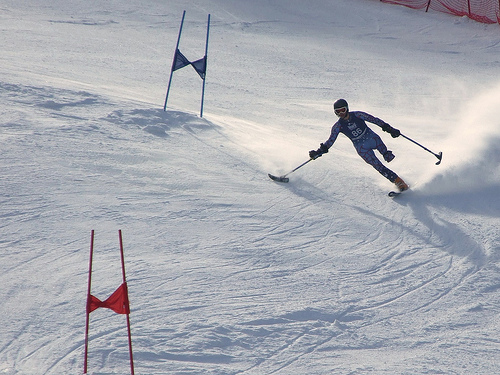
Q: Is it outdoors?
A: Yes, it is outdoors.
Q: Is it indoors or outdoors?
A: It is outdoors.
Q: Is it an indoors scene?
A: No, it is outdoors.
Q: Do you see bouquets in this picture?
A: No, there are no bouquets.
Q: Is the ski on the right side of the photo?
A: Yes, the ski is on the right of the image.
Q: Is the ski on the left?
A: No, the ski is on the right of the image.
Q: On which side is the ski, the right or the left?
A: The ski is on the right of the image.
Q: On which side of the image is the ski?
A: The ski is on the right of the image.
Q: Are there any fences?
A: Yes, there is a fence.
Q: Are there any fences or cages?
A: Yes, there is a fence.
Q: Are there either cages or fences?
A: Yes, there is a fence.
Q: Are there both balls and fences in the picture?
A: No, there is a fence but no balls.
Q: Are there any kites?
A: No, there are no kites.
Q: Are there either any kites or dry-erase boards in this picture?
A: No, there are no kites or dry-erase boards.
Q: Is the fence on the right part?
A: Yes, the fence is on the right of the image.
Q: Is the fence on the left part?
A: No, the fence is on the right of the image.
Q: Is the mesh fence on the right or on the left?
A: The fence is on the right of the image.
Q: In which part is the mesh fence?
A: The fence is on the right of the image.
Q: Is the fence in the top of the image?
A: Yes, the fence is in the top of the image.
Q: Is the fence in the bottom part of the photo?
A: No, the fence is in the top of the image.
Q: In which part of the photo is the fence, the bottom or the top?
A: The fence is in the top of the image.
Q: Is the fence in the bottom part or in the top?
A: The fence is in the top of the image.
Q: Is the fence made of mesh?
A: Yes, the fence is made of mesh.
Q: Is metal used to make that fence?
A: No, the fence is made of mesh.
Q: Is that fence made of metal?
A: No, the fence is made of mesh.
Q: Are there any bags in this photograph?
A: No, there are no bags.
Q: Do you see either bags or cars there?
A: No, there are no bags or cars.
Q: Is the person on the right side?
A: Yes, the person is on the right of the image.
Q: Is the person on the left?
A: No, the person is on the right of the image.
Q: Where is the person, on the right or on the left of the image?
A: The person is on the right of the image.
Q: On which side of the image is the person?
A: The person is on the right of the image.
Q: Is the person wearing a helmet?
A: Yes, the person is wearing a helmet.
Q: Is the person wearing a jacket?
A: No, the person is wearing a helmet.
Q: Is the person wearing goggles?
A: Yes, the person is wearing goggles.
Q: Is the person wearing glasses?
A: No, the person is wearing goggles.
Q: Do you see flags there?
A: Yes, there is a flag.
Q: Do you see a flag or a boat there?
A: Yes, there is a flag.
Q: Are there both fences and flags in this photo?
A: Yes, there are both a flag and a fence.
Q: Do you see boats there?
A: No, there are no boats.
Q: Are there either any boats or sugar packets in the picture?
A: No, there are no boats or sugar packets.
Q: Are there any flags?
A: Yes, there is a flag.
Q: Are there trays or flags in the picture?
A: Yes, there is a flag.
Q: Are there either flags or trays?
A: Yes, there is a flag.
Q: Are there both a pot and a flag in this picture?
A: No, there is a flag but no pots.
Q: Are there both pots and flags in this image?
A: No, there is a flag but no pots.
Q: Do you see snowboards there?
A: No, there are no snowboards.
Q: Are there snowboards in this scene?
A: No, there are no snowboards.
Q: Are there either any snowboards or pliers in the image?
A: No, there are no snowboards or pliers.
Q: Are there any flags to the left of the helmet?
A: Yes, there is a flag to the left of the helmet.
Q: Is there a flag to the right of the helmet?
A: No, the flag is to the left of the helmet.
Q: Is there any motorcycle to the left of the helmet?
A: No, there is a flag to the left of the helmet.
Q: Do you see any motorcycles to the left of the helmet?
A: No, there is a flag to the left of the helmet.